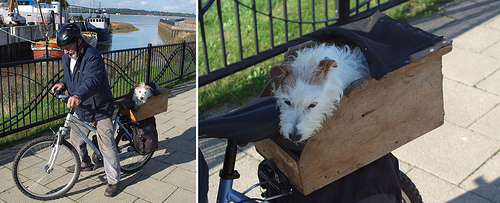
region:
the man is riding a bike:
[22, 22, 172, 197]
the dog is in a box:
[87, 67, 212, 167]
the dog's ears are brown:
[262, 42, 407, 154]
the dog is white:
[238, 41, 423, 196]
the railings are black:
[0, 37, 231, 148]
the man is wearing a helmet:
[34, 14, 126, 80]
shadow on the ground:
[129, 107, 217, 187]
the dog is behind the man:
[115, 79, 183, 126]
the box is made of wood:
[97, 72, 196, 123]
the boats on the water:
[4, 12, 159, 81]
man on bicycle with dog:
[13, 16, 170, 200]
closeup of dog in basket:
[258, 34, 368, 148]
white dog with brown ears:
[261, 47, 349, 99]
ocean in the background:
[3, 3, 195, 63]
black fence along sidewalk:
[2, 39, 218, 131]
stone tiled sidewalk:
[392, 34, 499, 163]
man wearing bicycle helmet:
[47, 16, 122, 201]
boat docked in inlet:
[3, 25, 67, 65]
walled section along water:
[150, 12, 195, 52]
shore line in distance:
[71, 2, 202, 25]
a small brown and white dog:
[264, 29, 378, 154]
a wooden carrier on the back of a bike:
[256, 11, 454, 201]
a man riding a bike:
[9, 19, 178, 189]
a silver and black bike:
[22, 84, 176, 197]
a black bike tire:
[6, 129, 84, 198]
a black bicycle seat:
[201, 92, 301, 142]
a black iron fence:
[0, 35, 193, 143]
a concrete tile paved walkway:
[4, 84, 193, 201]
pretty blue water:
[110, 13, 164, 52]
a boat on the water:
[79, 4, 123, 39]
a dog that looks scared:
[243, 40, 460, 186]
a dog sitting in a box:
[250, 40, 441, 180]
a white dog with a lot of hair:
[266, 47, 381, 148]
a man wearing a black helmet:
[50, 22, 95, 80]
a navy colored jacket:
[55, 54, 111, 122]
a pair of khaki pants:
[70, 115, 128, 194]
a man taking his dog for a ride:
[9, 37, 186, 201]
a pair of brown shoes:
[85, 176, 132, 198]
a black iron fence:
[207, 0, 286, 47]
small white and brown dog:
[264, 43, 373, 153]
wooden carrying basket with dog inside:
[234, 15, 461, 202]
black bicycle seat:
[196, 91, 295, 150]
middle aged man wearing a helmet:
[46, 17, 134, 199]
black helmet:
[49, 21, 84, 48]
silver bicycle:
[4, 84, 175, 201]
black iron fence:
[1, 34, 197, 141]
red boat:
[25, 25, 100, 62]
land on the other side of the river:
[68, 4, 199, 19]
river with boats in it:
[0, 0, 160, 55]